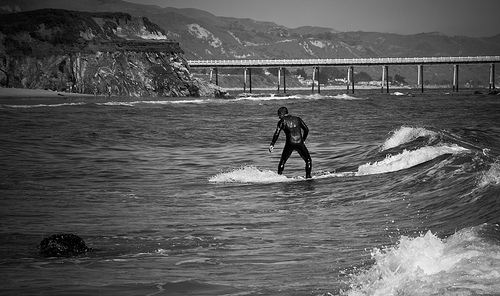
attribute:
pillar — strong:
[438, 54, 476, 88]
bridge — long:
[193, 53, 498, 95]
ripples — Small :
[226, 254, 341, 294]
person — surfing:
[256, 79, 372, 194]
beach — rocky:
[0, 85, 192, 105]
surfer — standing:
[251, 92, 315, 183]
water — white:
[175, 194, 270, 269]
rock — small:
[33, 227, 102, 262]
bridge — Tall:
[184, 50, 499, 100]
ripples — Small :
[213, 261, 263, 291]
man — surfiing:
[268, 104, 320, 182]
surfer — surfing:
[266, 103, 316, 180]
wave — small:
[403, 127, 486, 214]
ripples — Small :
[117, 249, 207, 291]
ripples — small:
[227, 219, 322, 274]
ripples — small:
[147, 205, 245, 251]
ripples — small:
[362, 176, 448, 216]